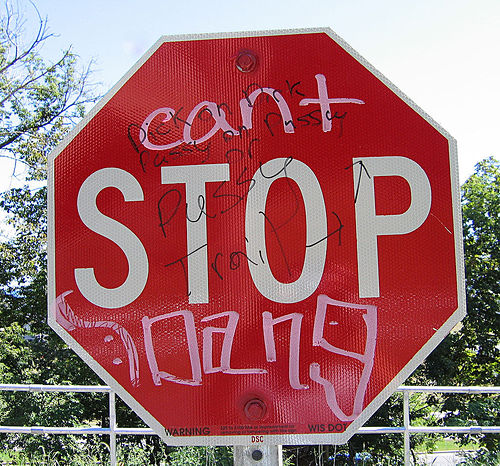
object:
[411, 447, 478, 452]
curbing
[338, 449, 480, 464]
road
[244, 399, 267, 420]
bolt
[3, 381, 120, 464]
metal fence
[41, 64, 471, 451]
graffiti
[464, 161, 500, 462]
trees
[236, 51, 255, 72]
bolt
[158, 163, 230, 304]
letter t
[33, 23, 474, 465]
stop sign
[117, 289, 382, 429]
graffiti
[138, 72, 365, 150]
graffiti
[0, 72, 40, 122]
branch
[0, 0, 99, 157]
tree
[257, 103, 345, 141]
graffiti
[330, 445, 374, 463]
flowers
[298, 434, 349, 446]
white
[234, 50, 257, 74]
metal bolt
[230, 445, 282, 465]
pole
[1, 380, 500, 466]
fence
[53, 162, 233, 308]
letter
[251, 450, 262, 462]
bolt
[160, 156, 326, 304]
graffiti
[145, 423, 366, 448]
edge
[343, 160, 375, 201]
graffiti